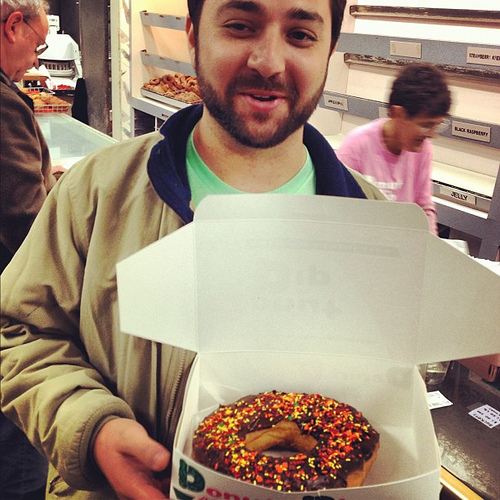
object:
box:
[111, 172, 500, 500]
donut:
[187, 383, 381, 500]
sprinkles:
[290, 395, 326, 418]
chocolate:
[205, 448, 234, 470]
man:
[0, 0, 453, 500]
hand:
[84, 408, 185, 500]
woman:
[335, 60, 453, 255]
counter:
[420, 363, 500, 499]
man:
[0, 0, 59, 273]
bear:
[193, 73, 329, 151]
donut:
[149, 75, 162, 87]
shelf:
[139, 9, 191, 31]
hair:
[184, 0, 212, 40]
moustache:
[235, 74, 293, 95]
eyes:
[281, 22, 320, 50]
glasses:
[19, 17, 49, 57]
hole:
[241, 413, 317, 458]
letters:
[175, 457, 208, 494]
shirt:
[176, 134, 320, 227]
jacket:
[0, 63, 72, 343]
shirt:
[337, 118, 441, 241]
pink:
[336, 116, 439, 237]